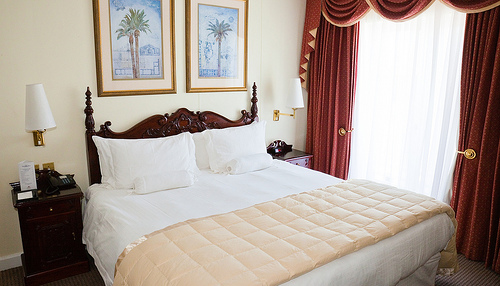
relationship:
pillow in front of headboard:
[91, 131, 202, 195] [79, 76, 266, 186]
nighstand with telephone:
[12, 182, 84, 278] [13, 153, 38, 198]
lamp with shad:
[22, 83, 57, 170] [17, 73, 55, 142]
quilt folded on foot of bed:
[108, 189, 453, 283] [69, 86, 461, 284]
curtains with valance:
[290, 4, 497, 260] [297, 5, 498, 81]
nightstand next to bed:
[272, 144, 308, 173] [69, 86, 461, 284]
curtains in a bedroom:
[290, 4, 497, 260] [0, 0, 500, 286]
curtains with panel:
[290, 4, 497, 260] [347, 10, 469, 209]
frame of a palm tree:
[92, 0, 176, 98] [111, 0, 158, 87]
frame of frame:
[92, 0, 176, 98] [92, 0, 176, 98]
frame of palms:
[182, 0, 250, 94] [100, 7, 234, 82]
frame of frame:
[182, 0, 250, 94] [182, 0, 250, 94]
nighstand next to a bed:
[40, 173, 76, 196] [69, 86, 461, 284]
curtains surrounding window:
[290, 4, 497, 260] [342, 31, 467, 190]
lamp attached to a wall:
[12, 77, 64, 167] [8, 5, 108, 176]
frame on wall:
[182, 0, 250, 94] [61, 1, 291, 120]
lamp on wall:
[22, 83, 57, 170] [5, 27, 90, 77]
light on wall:
[265, 70, 327, 136] [244, 11, 341, 131]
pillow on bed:
[82, 125, 209, 196] [31, 101, 425, 281]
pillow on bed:
[201, 106, 294, 175] [72, 120, 398, 273]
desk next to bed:
[8, 156, 121, 283] [58, 96, 460, 276]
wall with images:
[7, 6, 289, 140] [86, 8, 288, 112]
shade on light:
[20, 89, 59, 124] [14, 82, 78, 178]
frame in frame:
[92, 0, 176, 98] [92, 0, 174, 95]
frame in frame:
[182, 0, 250, 94] [182, 1, 252, 94]